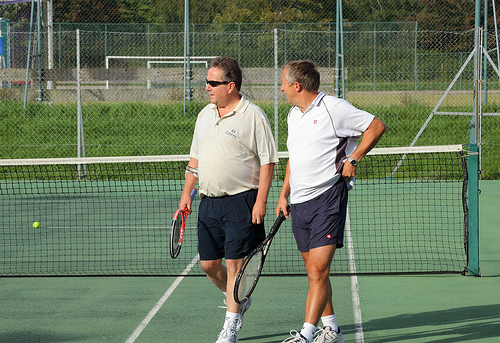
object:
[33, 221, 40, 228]
tennis ball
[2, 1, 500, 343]
court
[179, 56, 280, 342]
man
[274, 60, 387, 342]
man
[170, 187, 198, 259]
tennis racket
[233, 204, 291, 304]
tennis racket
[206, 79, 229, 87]
sunglasses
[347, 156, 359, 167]
wrist watch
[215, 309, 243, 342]
shoes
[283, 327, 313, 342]
shoes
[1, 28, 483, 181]
fence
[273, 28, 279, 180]
post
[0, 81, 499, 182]
grass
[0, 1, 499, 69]
trees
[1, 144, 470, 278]
tennis net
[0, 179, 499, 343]
ground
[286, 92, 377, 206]
polo shirt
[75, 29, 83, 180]
pole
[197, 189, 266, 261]
shorts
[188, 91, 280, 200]
polo shirt